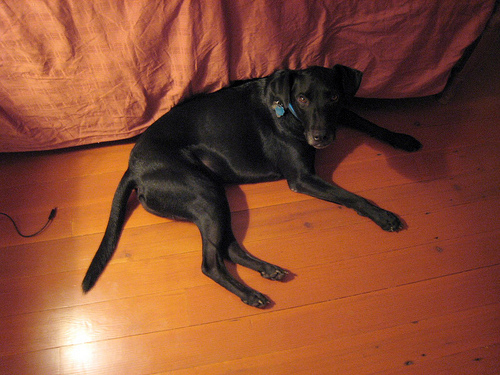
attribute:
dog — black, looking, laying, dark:
[251, 75, 339, 158]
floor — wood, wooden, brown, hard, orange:
[331, 253, 403, 311]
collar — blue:
[279, 100, 293, 121]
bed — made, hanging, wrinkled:
[145, 14, 199, 47]